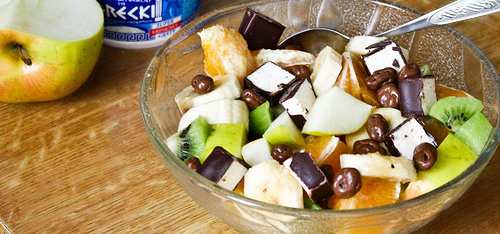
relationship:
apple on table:
[0, 1, 103, 106] [1, 0, 497, 231]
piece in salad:
[198, 25, 257, 81] [171, 17, 497, 211]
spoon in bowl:
[282, 1, 499, 50] [136, 2, 500, 233]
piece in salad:
[167, 117, 207, 160] [171, 17, 497, 211]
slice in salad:
[304, 87, 374, 136] [171, 17, 497, 211]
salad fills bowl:
[171, 17, 497, 211] [136, 2, 500, 233]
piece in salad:
[242, 160, 304, 208] [171, 17, 497, 211]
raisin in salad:
[190, 75, 215, 94] [171, 17, 497, 211]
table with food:
[1, 0, 497, 231] [171, 17, 497, 211]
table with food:
[1, 0, 497, 231] [0, 1, 103, 106]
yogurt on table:
[99, 1, 199, 49] [1, 0, 497, 231]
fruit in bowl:
[171, 17, 497, 211] [136, 2, 500, 233]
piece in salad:
[304, 87, 374, 136] [171, 17, 497, 211]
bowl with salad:
[136, 2, 500, 233] [171, 17, 497, 211]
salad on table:
[171, 17, 497, 211] [1, 0, 497, 231]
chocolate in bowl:
[240, 8, 287, 49] [136, 2, 500, 233]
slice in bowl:
[198, 25, 257, 81] [136, 2, 500, 233]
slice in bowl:
[334, 176, 401, 208] [136, 2, 500, 233]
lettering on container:
[104, 3, 155, 20] [99, 1, 199, 49]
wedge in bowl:
[268, 109, 304, 146] [136, 2, 500, 233]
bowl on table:
[136, 2, 500, 233] [1, 0, 497, 231]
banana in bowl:
[242, 160, 304, 208] [136, 2, 500, 233]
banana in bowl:
[312, 43, 344, 93] [136, 2, 500, 233]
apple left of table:
[0, 1, 103, 106] [1, 0, 497, 231]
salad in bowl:
[171, 17, 497, 211] [136, 2, 500, 233]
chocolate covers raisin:
[413, 140, 439, 170] [190, 75, 215, 94]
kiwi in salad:
[432, 95, 484, 128] [171, 17, 497, 211]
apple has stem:
[0, 1, 103, 106] [15, 45, 34, 66]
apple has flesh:
[0, 1, 103, 106] [1, 0, 104, 42]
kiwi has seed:
[432, 95, 484, 128] [460, 113, 466, 120]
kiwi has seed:
[432, 95, 484, 128] [447, 124, 453, 130]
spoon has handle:
[282, 1, 499, 50] [360, 1, 499, 47]